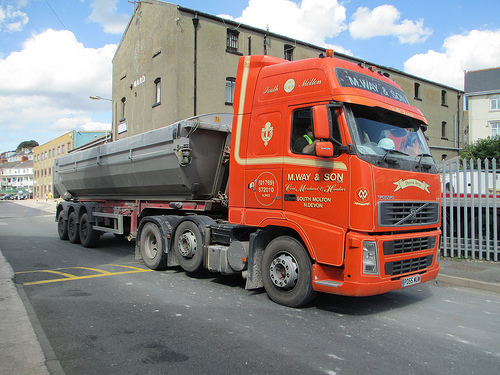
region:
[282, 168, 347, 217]
logo and location text for trucking company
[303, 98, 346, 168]
side-view mirrors for truck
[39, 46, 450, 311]
large industrial truck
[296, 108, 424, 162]
people sitting in cab of truck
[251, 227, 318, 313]
large black tires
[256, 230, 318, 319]
big industrial black rubber wheels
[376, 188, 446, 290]
grilles for ventilation on truck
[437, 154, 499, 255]
white picket style fence on sidewalk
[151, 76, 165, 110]
window on side of tall building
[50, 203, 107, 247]
three of the truck's rear wheels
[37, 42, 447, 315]
orange truck on the street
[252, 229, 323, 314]
black tire on a truck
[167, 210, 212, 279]
black tire on a truck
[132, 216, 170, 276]
black tire on a truck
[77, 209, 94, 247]
black tire on a truck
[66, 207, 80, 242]
black tire on a truck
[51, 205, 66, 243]
black tire on a truck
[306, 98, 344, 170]
side view mirror on truck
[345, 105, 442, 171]
windshield on a truck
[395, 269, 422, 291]
license plate on a truck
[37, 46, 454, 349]
a truck on the road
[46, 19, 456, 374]
an orange truck cab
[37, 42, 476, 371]
an orange truck cab on the road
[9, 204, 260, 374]
yellow lines on the road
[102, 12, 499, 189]
a building with windows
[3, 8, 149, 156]
clouds in the blue sky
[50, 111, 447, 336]
a truck with a lot of tires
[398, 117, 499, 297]
a white fence along the road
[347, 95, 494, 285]
a tall white fence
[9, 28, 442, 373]
a road on the truck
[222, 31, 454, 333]
the truck is orange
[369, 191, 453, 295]
front grill is black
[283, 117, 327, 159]
man sitting in passenger seat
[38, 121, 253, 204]
back of truck is gray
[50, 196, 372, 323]
truck wheels are black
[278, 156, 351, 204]
letters on truck are yellow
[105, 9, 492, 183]
the building is brown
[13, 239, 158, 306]
lines in road are yellow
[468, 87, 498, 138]
the building is white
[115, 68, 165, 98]
white letters on building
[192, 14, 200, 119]
A drain on the building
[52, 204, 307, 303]
6 tires on the truck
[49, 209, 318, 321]
Five tires on the ground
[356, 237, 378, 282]
the headlight of the truck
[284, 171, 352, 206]
The logo on the door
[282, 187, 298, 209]
The door handle on the truck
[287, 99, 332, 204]
The man in the passanger seat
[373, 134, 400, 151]
a white hard hat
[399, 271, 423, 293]
the front liscense plate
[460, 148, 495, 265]
A white gate on the sidewalk